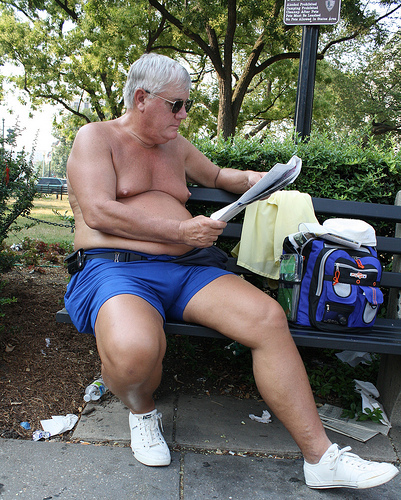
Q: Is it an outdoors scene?
A: Yes, it is outdoors.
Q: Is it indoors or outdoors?
A: It is outdoors.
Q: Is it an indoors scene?
A: No, it is outdoors.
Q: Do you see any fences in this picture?
A: No, there are no fences.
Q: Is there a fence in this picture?
A: No, there are no fences.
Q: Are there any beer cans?
A: No, there are no beer cans.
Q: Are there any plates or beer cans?
A: No, there are no beer cans or plates.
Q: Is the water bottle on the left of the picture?
A: Yes, the water bottle is on the left of the image.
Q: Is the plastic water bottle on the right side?
A: No, the water bottle is on the left of the image.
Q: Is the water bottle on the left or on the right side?
A: The water bottle is on the left of the image.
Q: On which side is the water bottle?
A: The water bottle is on the left of the image.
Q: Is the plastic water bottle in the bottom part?
A: Yes, the water bottle is in the bottom of the image.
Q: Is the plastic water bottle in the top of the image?
A: No, the water bottle is in the bottom of the image.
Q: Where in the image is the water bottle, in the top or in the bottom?
A: The water bottle is in the bottom of the image.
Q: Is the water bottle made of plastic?
A: Yes, the water bottle is made of plastic.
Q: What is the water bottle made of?
A: The water bottle is made of plastic.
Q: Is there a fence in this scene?
A: No, there are no fences.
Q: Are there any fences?
A: No, there are no fences.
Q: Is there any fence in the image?
A: No, there are no fences.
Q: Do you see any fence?
A: No, there are no fences.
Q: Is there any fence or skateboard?
A: No, there are no fences or skateboards.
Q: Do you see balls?
A: No, there are no balls.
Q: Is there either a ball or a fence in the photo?
A: No, there are no balls or fences.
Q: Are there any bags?
A: Yes, there is a bag.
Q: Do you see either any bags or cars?
A: Yes, there is a bag.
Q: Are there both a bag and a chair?
A: No, there is a bag but no chairs.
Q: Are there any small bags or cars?
A: Yes, there is a small bag.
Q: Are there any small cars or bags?
A: Yes, there is a small bag.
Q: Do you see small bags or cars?
A: Yes, there is a small bag.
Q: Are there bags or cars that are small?
A: Yes, the bag is small.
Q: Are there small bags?
A: Yes, there is a small bag.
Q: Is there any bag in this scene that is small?
A: Yes, there is a bag that is small.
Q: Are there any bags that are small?
A: Yes, there is a bag that is small.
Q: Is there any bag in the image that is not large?
A: Yes, there is a small bag.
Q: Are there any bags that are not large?
A: Yes, there is a small bag.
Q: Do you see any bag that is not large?
A: Yes, there is a small bag.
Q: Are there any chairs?
A: No, there are no chairs.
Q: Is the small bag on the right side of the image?
A: Yes, the bag is on the right of the image.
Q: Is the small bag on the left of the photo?
A: No, the bag is on the right of the image.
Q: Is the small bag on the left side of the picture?
A: No, the bag is on the right of the image.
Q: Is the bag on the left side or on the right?
A: The bag is on the right of the image.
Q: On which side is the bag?
A: The bag is on the right of the image.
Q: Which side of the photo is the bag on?
A: The bag is on the right of the image.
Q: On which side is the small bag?
A: The bag is on the right of the image.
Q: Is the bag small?
A: Yes, the bag is small.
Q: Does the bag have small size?
A: Yes, the bag is small.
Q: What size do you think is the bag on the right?
A: The bag is small.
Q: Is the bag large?
A: No, the bag is small.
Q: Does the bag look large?
A: No, the bag is small.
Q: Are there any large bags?
A: No, there is a bag but it is small.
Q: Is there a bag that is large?
A: No, there is a bag but it is small.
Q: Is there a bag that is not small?
A: No, there is a bag but it is small.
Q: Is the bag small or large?
A: The bag is small.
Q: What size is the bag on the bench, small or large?
A: The bag is small.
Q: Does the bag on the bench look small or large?
A: The bag is small.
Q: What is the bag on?
A: The bag is on the bench.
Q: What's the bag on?
A: The bag is on the bench.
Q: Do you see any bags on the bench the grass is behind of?
A: Yes, there is a bag on the bench.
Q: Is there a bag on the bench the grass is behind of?
A: Yes, there is a bag on the bench.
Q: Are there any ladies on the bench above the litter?
A: No, there is a bag on the bench.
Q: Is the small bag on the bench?
A: Yes, the bag is on the bench.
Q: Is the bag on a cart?
A: No, the bag is on the bench.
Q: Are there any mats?
A: No, there are no mats.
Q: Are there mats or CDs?
A: No, there are no mats or cds.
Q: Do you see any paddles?
A: No, there are no paddles.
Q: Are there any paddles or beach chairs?
A: No, there are no paddles or beach chairs.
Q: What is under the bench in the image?
A: The litter is under the bench.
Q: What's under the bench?
A: The litter is under the bench.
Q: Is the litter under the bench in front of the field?
A: Yes, the litter is under the bench.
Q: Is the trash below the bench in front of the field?
A: Yes, the trash is below the bench.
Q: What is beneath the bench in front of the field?
A: The litter is beneath the bench.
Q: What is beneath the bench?
A: The litter is beneath the bench.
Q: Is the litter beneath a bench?
A: Yes, the litter is beneath a bench.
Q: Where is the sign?
A: The sign is in the park.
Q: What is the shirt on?
A: The shirt is on the bench.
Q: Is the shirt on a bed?
A: No, the shirt is on the bench.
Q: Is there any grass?
A: Yes, there is grass.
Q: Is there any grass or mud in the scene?
A: Yes, there is grass.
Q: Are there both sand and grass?
A: No, there is grass but no sand.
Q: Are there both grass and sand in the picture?
A: No, there is grass but no sand.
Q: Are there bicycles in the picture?
A: No, there are no bicycles.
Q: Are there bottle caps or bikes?
A: No, there are no bikes or bottle caps.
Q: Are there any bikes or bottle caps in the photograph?
A: No, there are no bikes or bottle caps.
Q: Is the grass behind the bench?
A: Yes, the grass is behind the bench.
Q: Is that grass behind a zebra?
A: No, the grass is behind the bench.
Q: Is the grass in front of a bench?
A: No, the grass is behind a bench.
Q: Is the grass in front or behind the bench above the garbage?
A: The grass is behind the bench.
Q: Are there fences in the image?
A: No, there are no fences.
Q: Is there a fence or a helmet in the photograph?
A: No, there are no fences or helmets.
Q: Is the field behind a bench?
A: Yes, the field is behind a bench.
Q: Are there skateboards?
A: No, there are no skateboards.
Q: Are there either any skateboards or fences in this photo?
A: No, there are no skateboards or fences.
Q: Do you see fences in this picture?
A: No, there are no fences.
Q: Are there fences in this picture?
A: No, there are no fences.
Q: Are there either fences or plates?
A: No, there are no fences or plates.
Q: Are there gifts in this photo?
A: No, there are no gifts.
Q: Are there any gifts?
A: No, there are no gifts.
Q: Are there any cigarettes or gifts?
A: No, there are no gifts or cigarettes.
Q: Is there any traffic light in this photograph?
A: No, there are no traffic lights.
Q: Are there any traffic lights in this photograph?
A: No, there are no traffic lights.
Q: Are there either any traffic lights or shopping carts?
A: No, there are no traffic lights or shopping carts.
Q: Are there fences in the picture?
A: No, there are no fences.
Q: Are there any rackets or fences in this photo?
A: No, there are no fences or rackets.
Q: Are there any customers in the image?
A: No, there are no customers.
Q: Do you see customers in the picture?
A: No, there are no customers.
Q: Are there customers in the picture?
A: No, there are no customers.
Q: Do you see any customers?
A: No, there are no customers.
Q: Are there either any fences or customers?
A: No, there are no customers or fences.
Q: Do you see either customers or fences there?
A: No, there are no customers or fences.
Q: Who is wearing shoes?
A: The man is wearing shoes.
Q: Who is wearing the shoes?
A: The man is wearing shoes.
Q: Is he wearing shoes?
A: Yes, the man is wearing shoes.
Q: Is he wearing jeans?
A: No, the man is wearing shoes.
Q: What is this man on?
A: The man is on the bench.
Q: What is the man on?
A: The man is on the bench.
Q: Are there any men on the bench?
A: Yes, there is a man on the bench.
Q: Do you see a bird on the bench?
A: No, there is a man on the bench.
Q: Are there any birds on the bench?
A: No, there is a man on the bench.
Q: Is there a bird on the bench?
A: No, there is a man on the bench.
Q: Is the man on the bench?
A: Yes, the man is on the bench.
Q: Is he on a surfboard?
A: No, the man is on the bench.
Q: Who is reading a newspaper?
A: The man is reading a newspaper.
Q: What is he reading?
A: The man is reading a newspaper.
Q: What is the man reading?
A: The man is reading a newspaper.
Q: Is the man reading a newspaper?
A: Yes, the man is reading a newspaper.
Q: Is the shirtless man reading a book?
A: No, the man is reading a newspaper.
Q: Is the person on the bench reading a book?
A: No, the man is reading a newspaper.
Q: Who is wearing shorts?
A: The man is wearing shorts.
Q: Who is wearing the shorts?
A: The man is wearing shorts.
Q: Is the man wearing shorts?
A: Yes, the man is wearing shorts.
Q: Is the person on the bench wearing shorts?
A: Yes, the man is wearing shorts.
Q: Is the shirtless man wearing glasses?
A: No, the man is wearing shorts.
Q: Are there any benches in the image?
A: Yes, there is a bench.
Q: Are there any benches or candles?
A: Yes, there is a bench.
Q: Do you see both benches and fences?
A: No, there is a bench but no fences.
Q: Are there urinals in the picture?
A: No, there are no urinals.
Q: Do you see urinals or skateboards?
A: No, there are no urinals or skateboards.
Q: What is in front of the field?
A: The bench is in front of the field.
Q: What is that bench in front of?
A: The bench is in front of the field.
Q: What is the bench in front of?
A: The bench is in front of the field.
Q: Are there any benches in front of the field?
A: Yes, there is a bench in front of the field.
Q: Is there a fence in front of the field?
A: No, there is a bench in front of the field.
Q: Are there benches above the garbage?
A: Yes, there is a bench above the garbage.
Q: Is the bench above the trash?
A: Yes, the bench is above the trash.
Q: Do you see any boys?
A: No, there are no boys.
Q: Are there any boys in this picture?
A: No, there are no boys.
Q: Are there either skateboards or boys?
A: No, there are no boys or skateboards.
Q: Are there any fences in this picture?
A: No, there are no fences.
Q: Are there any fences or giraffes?
A: No, there are no fences or giraffes.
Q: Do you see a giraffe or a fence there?
A: No, there are no fences or giraffes.